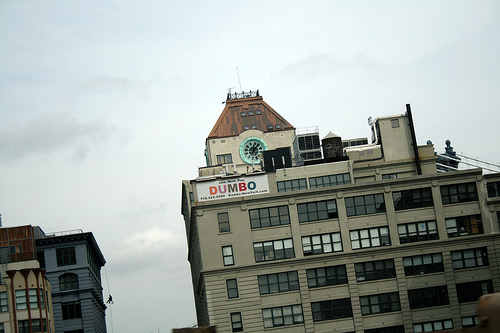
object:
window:
[56, 273, 77, 291]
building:
[0, 225, 110, 332]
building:
[179, 85, 496, 331]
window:
[238, 134, 271, 166]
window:
[307, 262, 350, 287]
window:
[220, 240, 237, 265]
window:
[215, 211, 233, 237]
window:
[225, 280, 237, 300]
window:
[229, 309, 245, 329]